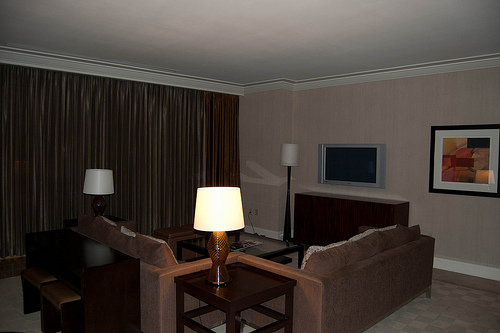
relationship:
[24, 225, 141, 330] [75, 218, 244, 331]
table behind couch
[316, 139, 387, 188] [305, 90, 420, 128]
television on wall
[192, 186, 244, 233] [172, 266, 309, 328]
lamp on table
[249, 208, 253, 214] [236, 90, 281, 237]
outlet on wall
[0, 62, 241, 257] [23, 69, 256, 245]
blinds of window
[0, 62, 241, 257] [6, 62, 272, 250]
blinds of window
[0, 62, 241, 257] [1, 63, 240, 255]
blinds of window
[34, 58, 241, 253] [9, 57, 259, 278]
blinds of window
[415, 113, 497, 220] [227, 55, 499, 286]
frame on wall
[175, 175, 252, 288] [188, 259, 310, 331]
lamp on table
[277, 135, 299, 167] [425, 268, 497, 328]
lamp on floor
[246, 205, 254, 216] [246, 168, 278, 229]
outlet on wall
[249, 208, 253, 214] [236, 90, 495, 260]
outlet on wall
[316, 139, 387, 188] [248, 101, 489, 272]
television on wall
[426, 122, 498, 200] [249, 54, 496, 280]
picture on wall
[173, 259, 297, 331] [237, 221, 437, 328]
table by couch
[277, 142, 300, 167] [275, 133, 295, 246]
lamp on lamp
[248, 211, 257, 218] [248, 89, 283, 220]
cord plugged into wall